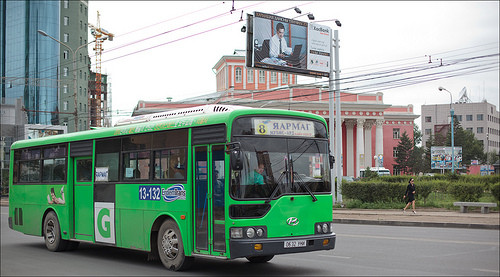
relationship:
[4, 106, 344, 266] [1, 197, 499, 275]
bus on road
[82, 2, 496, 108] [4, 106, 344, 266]
sky above bus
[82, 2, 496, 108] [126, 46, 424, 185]
sky above building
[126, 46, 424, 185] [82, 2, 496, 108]
building below sky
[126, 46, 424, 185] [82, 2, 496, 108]
building under sky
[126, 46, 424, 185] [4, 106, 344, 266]
building near bus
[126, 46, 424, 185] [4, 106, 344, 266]
building close to bus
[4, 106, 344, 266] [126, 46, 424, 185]
bus near building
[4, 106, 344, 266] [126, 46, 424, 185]
bus under building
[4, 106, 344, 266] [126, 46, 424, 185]
bus below building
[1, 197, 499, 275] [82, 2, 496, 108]
road below sky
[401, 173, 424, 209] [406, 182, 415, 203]
woman wearing dress